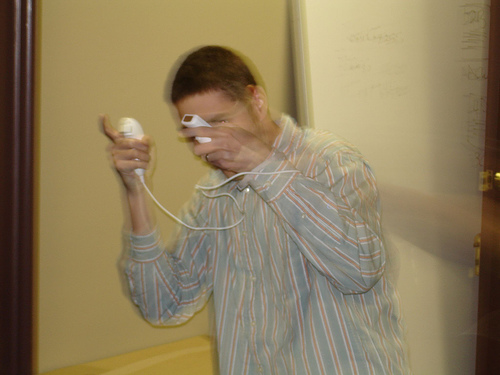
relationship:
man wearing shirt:
[102, 45, 412, 374] [121, 112, 410, 374]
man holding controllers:
[102, 45, 412, 374] [118, 113, 303, 230]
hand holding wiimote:
[177, 126, 274, 177] [181, 113, 215, 144]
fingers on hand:
[178, 119, 234, 170] [177, 126, 274, 177]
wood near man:
[0, 0, 41, 374] [102, 45, 412, 374]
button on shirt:
[243, 186, 251, 194] [121, 112, 410, 374]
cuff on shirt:
[239, 148, 299, 202] [121, 112, 410, 374]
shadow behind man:
[283, 0, 298, 127] [102, 45, 412, 374]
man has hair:
[102, 45, 412, 374] [171, 45, 259, 133]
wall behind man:
[36, 0, 299, 375] [102, 45, 412, 374]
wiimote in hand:
[181, 113, 215, 144] [177, 126, 274, 177]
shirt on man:
[121, 112, 410, 374] [102, 45, 412, 374]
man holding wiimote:
[102, 45, 412, 374] [181, 113, 215, 144]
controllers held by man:
[118, 113, 303, 230] [102, 45, 412, 374]